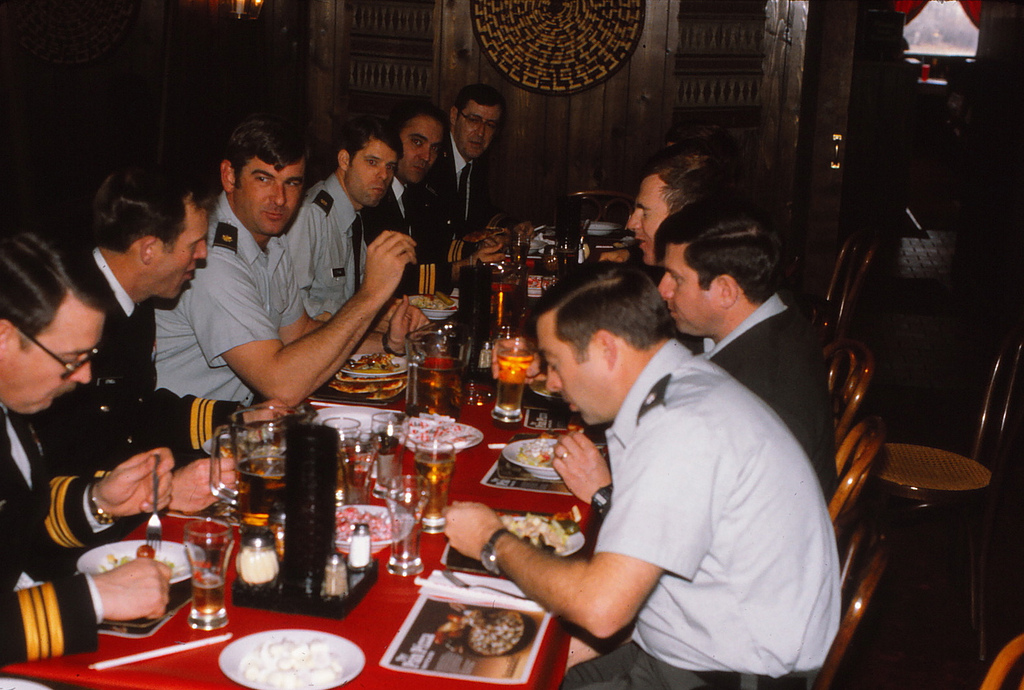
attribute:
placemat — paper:
[357, 500, 569, 688]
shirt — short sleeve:
[575, 334, 841, 661]